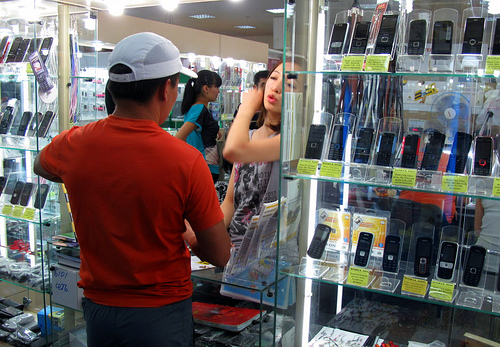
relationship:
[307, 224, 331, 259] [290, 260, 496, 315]
cellphone on shelf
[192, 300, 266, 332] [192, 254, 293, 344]
book under counter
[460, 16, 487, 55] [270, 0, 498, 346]
cellphone on display case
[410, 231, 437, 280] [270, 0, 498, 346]
phone inside display case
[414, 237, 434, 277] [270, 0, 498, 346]
phone inside display case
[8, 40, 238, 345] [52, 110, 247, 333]
man wearing shirt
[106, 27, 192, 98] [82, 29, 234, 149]
hat on head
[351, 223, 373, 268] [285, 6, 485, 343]
phone on shelf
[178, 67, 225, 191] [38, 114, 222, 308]
woman with red shirt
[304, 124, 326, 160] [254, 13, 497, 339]
phone with shelf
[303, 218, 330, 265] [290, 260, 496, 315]
cellphone on shelf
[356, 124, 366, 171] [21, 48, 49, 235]
phone in case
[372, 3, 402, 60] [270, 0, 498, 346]
phone in display case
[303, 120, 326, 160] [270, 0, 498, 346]
phone in display case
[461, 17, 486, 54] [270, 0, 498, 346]
cellphone in display case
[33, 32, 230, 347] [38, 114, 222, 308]
man wearing red shirt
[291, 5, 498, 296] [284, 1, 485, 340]
cellphones in case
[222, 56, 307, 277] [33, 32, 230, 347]
she talking man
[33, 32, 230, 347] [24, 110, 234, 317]
man wearing red shirt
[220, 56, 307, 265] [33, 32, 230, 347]
she talking to man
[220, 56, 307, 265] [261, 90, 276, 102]
she with lipstick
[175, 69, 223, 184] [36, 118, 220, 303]
woman with shirt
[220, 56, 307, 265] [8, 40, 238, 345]
she in front of man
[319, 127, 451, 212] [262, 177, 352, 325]
phone inside display case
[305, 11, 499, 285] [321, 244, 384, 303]
cell phones have physical keyboards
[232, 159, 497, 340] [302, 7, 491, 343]
these are not smart phones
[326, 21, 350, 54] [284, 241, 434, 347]
cell phones in a display case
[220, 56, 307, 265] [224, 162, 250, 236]
she arm over shoulder